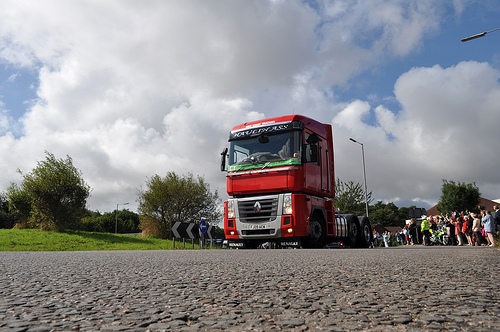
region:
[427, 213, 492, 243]
people standing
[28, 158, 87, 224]
a green bush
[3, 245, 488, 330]
the street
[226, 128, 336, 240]
a red truck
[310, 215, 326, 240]
the wheel on the truck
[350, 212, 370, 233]
the wheels on the back of the truck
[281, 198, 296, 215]
the headlights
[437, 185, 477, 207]
the bush is green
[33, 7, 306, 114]
the clouds are white in the sky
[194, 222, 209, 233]
a white arrow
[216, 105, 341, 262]
a large semi truck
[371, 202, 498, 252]
a group of people standing by the truck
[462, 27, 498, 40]
the lamp of a light post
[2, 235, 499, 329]
black rocks on the ground to make a road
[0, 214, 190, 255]
patch of green grass on the ground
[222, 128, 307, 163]
windshield of the truck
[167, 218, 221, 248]
arrows on the signs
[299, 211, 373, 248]
black rubber tires on the truck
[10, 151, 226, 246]
green bushy trees in the grass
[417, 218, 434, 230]
yellow jacket on a person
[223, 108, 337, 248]
cab of a red semi truck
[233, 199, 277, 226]
silver grill of a vehicle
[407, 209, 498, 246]
small crowd of people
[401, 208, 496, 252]
gathering of people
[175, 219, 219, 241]
black and white directional signs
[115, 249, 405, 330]
rough paved street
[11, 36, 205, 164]
white fluffy clouds in a blue sky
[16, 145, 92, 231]
tree is bending in the wind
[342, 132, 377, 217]
tall metal street lamp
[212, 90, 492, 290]
group of people near large red truck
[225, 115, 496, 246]
A crowd of people near a large red truck.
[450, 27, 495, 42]
The top of a streetlight.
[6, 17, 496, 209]
Billowing clouds in the sky.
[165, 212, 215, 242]
Black and white arrow signs.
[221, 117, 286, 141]
The truck has white lettering above the front window.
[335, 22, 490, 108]
A patch of blue sky.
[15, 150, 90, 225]
A tree on a small hill.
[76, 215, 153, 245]
A shadow of the tree on the grass.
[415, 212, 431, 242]
A person wearing a green jacket.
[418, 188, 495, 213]
The roof of a building behind a tree.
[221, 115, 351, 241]
red truck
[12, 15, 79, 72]
white clouds against blue sky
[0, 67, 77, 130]
white clouds against blue sky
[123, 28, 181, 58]
white clouds against blue sky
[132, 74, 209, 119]
white clouds against blue sky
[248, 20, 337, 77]
white clouds against blue sky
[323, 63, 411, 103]
white clouds against blue sky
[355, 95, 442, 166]
white clouds against blue sky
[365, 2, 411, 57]
white clouds against blue sky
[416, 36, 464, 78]
white clouds against blue sky